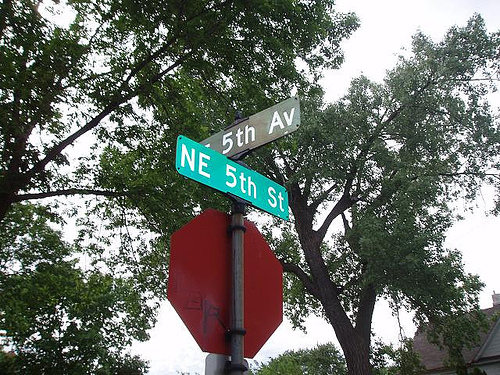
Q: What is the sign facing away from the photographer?
A: A stop sign.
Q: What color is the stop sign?
A: Red.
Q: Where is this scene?
A: NE 5th St.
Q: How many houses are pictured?
A: One.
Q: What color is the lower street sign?
A: Green.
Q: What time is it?
A: Day time.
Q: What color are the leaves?
A: Green.